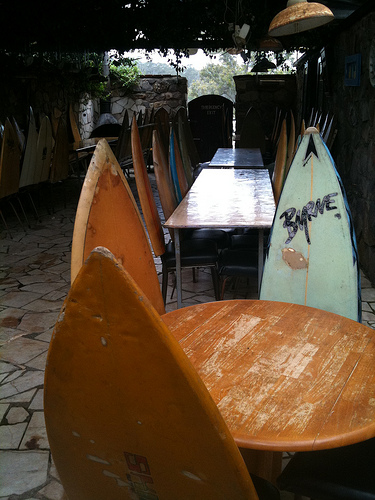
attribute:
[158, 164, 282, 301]
dining table — rectangle, brown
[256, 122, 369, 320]
board — white, blue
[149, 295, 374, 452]
table — Scratched, scuffed, wooden, light brown, round, cafe,  long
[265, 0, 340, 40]
lamp — hanging, overhead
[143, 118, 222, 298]
chair — half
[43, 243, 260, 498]
yellow surfboard —  yellow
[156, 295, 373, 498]
table — round, old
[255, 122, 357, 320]
board — white, yellow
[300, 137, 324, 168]
emblem — painted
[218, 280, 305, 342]
table — round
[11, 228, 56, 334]
ground — flagstone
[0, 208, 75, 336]
stones — rock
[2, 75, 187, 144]
stone wall — exterior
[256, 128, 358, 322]
dining chair — white, surfboard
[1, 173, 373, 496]
floor — light grey, stone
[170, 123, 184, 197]
border — blue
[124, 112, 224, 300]
chair — old surfboard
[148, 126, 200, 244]
chair — old surfboard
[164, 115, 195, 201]
chair — old surfboard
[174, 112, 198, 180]
chair — old surfboard